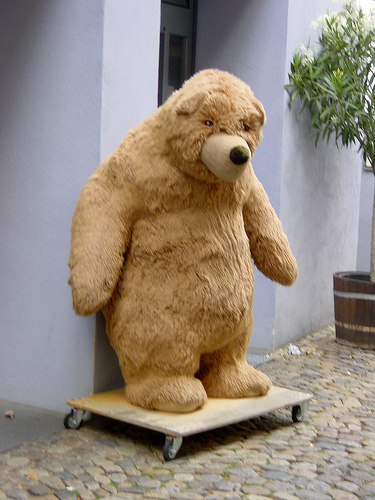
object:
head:
[164, 67, 266, 189]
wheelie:
[61, 387, 313, 462]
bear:
[66, 67, 299, 415]